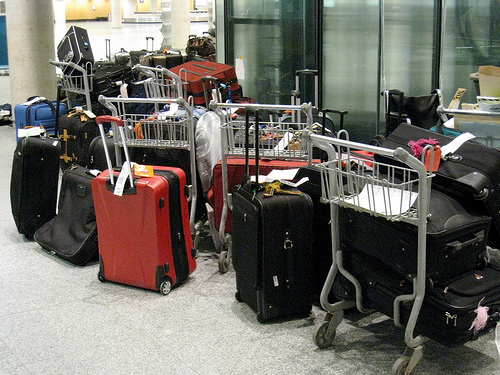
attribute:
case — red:
[89, 162, 198, 293]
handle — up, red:
[95, 114, 136, 187]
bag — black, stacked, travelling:
[327, 174, 488, 285]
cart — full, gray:
[306, 130, 438, 373]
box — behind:
[468, 64, 499, 102]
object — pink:
[409, 138, 438, 159]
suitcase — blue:
[13, 101, 68, 140]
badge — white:
[113, 161, 134, 196]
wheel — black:
[313, 321, 336, 351]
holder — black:
[243, 104, 262, 192]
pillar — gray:
[3, 3, 59, 132]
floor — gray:
[3, 127, 498, 374]